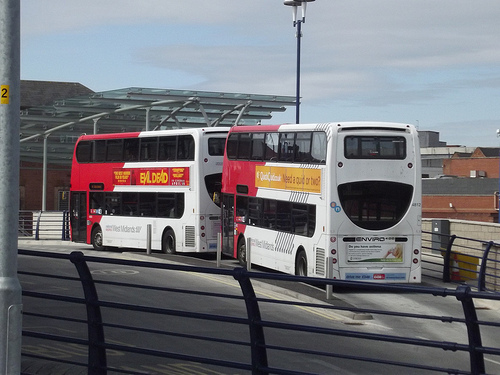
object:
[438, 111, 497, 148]
clouds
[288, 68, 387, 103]
cloud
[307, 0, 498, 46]
cloud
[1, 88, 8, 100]
number 2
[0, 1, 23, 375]
pole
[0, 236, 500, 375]
ground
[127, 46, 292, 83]
clouds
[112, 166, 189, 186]
advertisement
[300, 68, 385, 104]
clouds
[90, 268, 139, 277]
white circle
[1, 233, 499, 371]
street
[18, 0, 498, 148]
blue sky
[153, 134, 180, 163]
windows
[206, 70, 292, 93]
white clouds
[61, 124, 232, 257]
bus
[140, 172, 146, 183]
gold letters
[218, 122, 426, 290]
bus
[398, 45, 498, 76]
clouds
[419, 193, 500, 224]
wall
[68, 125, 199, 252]
bus`s front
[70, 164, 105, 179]
red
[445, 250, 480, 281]
bin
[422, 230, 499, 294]
railing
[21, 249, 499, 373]
rail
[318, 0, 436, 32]
clouds